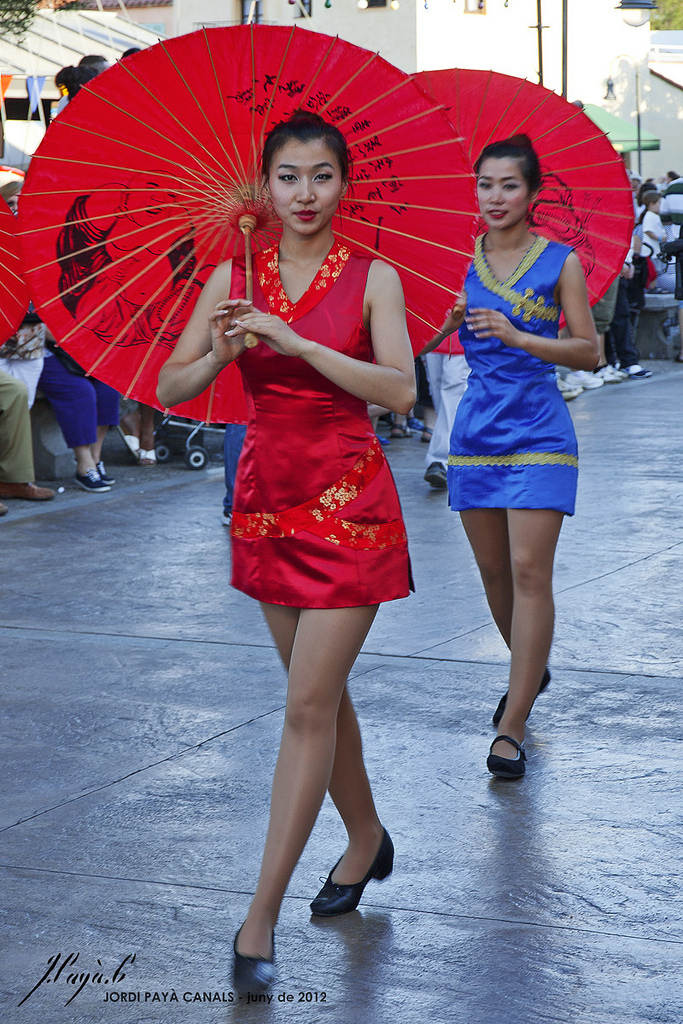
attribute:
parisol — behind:
[407, 63, 633, 357]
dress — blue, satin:
[452, 234, 582, 513]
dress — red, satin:
[226, 244, 425, 610]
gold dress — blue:
[444, 233, 577, 514]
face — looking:
[261, 109, 347, 236]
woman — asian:
[419, 134, 600, 779]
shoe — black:
[310, 823, 395, 917]